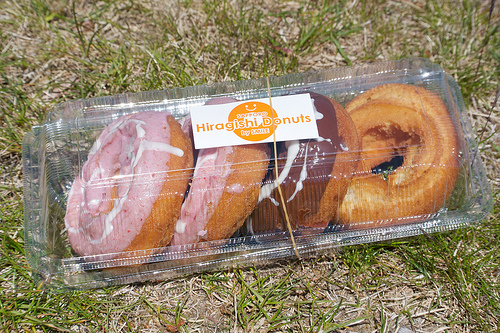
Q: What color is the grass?
A: Green.